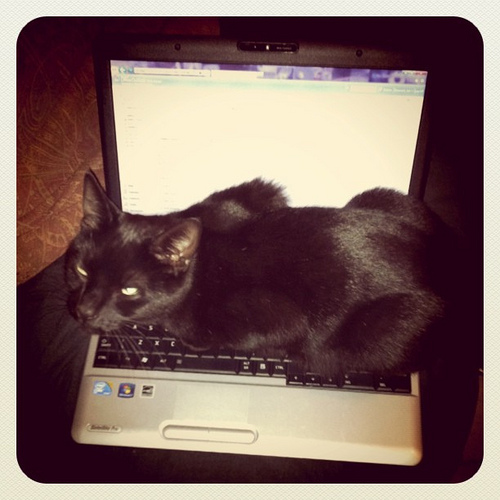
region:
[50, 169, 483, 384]
A CAT ON A LAPTOP.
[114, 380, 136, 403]
A WINDOWS LOGO STICKER.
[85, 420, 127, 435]
THE MAKE AND MODEL OF THE LAPTOP STICKER.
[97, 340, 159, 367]
THE KEYS ON THE KEYBOARD ARE BLACK.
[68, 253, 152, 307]
THE EYES OF THE CAT ARE NARROW.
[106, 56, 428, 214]
A WEB PAGE IS DISPLAYED ON THE SCREEN.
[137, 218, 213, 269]
THE CATS EAR IS PERKED UP.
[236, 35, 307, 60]
A SMALL WEBCAM AT THE TOP OF THE COMPUTER.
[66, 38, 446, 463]
cat sitting on laptop keyboard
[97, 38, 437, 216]
glowing screen of laptop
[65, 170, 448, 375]
black fur on cat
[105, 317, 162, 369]
whiskers on cat cheek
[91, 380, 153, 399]
three stickers on laptop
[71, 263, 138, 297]
partially closed green eyes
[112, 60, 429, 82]
image on top of screen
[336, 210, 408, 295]
light reflection on fur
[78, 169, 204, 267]
two ears on head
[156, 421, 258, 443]
oblong button on laptop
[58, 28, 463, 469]
A cat on top of a laptop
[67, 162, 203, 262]
Two ears on cat's head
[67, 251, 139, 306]
A pair of cat eyes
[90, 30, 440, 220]
The laptop screen is turned on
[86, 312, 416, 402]
Black keys on laptop keyboard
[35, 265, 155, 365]
Whiskers on the cat's face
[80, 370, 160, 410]
Three stickers on the laptop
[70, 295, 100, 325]
Nose on cat's face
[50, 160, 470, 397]
The cat is black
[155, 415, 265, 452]
The mouse button of a laptop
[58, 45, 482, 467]
a black cat resting on a laptop computer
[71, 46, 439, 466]
an open laptop computer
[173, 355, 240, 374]
a computer space bar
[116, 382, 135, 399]
a Microsoft Windows logo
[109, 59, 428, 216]
a computer display screen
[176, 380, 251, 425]
a computer track pad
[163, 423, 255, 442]
a computer track pad button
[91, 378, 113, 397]
an Intel sticker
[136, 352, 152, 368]
a black Windows logo key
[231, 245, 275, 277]
Black fur of the cat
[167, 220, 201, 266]
Left ear of the cat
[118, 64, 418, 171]
Part of the screen on the laptop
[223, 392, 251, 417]
Gray part of the laptop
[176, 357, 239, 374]
A small black space key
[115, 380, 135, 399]
Microsoft sticker on laptop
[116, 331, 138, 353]
Whites whiskers of cat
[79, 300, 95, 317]
Black nose of cat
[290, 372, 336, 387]
Bottom arrow keys on laptop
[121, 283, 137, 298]
Left yellow eye of cat